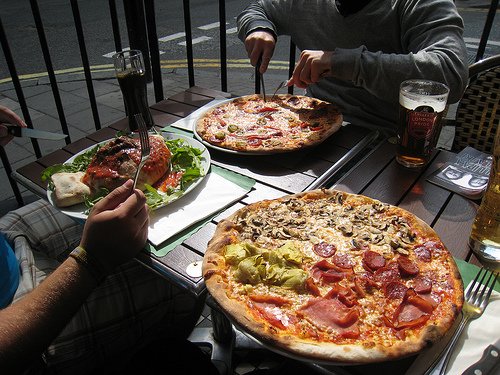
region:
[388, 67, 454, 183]
Nearly full glass of beer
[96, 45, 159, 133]
Beer three-quarters full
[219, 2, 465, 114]
Disembodied person in grey jacket cutting a piece of pizza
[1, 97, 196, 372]
Man with blue shirt and plaid pants prepares to cut into his dinner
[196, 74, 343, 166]
A medium-sized pizza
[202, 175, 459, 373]
Large pizza with different sections of toppings: Ham, pepperoni, mushrooms, and artichokes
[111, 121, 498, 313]
Two square tables pushed together, slats running perpendicular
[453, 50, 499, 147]
Partial glimpse of a chair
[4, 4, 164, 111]
Black metal fencing separating eating area from sidewalk and street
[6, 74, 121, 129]
Brick sidewalk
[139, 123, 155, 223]
man is holding a fork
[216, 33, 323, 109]
man is cutting with a fork and knife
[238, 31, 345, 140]
man is cutting pizza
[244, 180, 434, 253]
mushrooms on half the pizza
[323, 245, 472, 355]
pepperoni on a quarter of pizza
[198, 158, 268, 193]
placemats are green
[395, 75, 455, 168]
glass is full of beer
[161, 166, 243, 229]
napkin next to plate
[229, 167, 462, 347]
pizza is uncut and whole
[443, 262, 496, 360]
fork next to the pizza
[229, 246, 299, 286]
several green artichoke hearts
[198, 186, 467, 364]
pizza with artichokes, ham, pepperoni, and mushrooms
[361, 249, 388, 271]
single piece of pepperoni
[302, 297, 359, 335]
piece of thinly sliced ham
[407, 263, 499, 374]
metal fork on a white napkin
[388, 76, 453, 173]
beer in a promotional glass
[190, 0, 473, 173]
person cutting into a pizza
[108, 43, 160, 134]
dark beer in a tall glass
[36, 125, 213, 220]
plate with a hearty Italian meal on it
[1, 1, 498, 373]
two people eating outside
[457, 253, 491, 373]
fork on the table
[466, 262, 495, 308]
tines on the fork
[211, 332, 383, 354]
crust on the pizza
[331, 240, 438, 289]
pepperoni slices on the pizza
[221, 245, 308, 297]
artichoke hearts on the pizza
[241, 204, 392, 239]
mushrooms on the pizza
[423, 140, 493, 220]
magazine on the table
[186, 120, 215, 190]
lettuce on the plate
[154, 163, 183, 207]
blob of tomato sauce on the plate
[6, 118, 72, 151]
knife blade in the man's hand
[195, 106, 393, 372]
the pizza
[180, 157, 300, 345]
the pizza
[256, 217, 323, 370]
the pizza